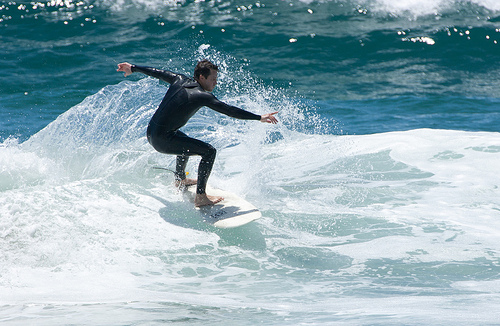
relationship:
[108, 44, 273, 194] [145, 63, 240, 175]
man wearing wet suit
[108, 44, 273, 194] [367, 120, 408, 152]
man in water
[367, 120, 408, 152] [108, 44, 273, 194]
water around man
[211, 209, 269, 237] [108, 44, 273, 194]
board beneath man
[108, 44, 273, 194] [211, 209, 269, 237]
man on board